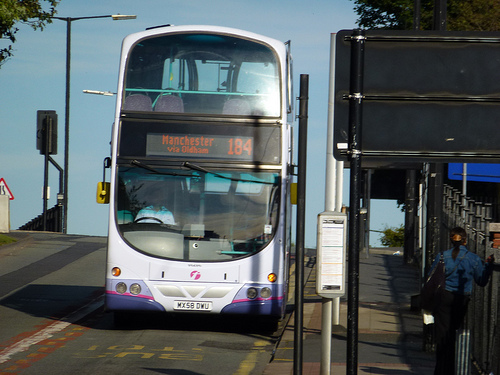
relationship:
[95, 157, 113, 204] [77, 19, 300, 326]
mirror of bus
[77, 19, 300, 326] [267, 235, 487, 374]
bus parked next to sidewalk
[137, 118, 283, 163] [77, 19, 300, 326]
destination indicator at front of bus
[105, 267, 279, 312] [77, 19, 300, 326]
headlights of bus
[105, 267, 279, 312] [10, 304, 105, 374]
headlights above red stripe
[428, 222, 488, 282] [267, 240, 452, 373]
person walking down sidewalk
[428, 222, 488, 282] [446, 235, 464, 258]
person wearing ponytail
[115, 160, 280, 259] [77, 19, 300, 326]
windshield on bus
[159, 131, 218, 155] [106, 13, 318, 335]
letters in middle of bus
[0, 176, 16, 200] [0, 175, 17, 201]
sign with border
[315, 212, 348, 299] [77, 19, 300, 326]
schedule of bus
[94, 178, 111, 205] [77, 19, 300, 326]
mirror on side of bus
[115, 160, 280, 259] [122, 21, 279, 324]
windshield on bus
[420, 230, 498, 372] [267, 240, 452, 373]
person walking on sidewalk